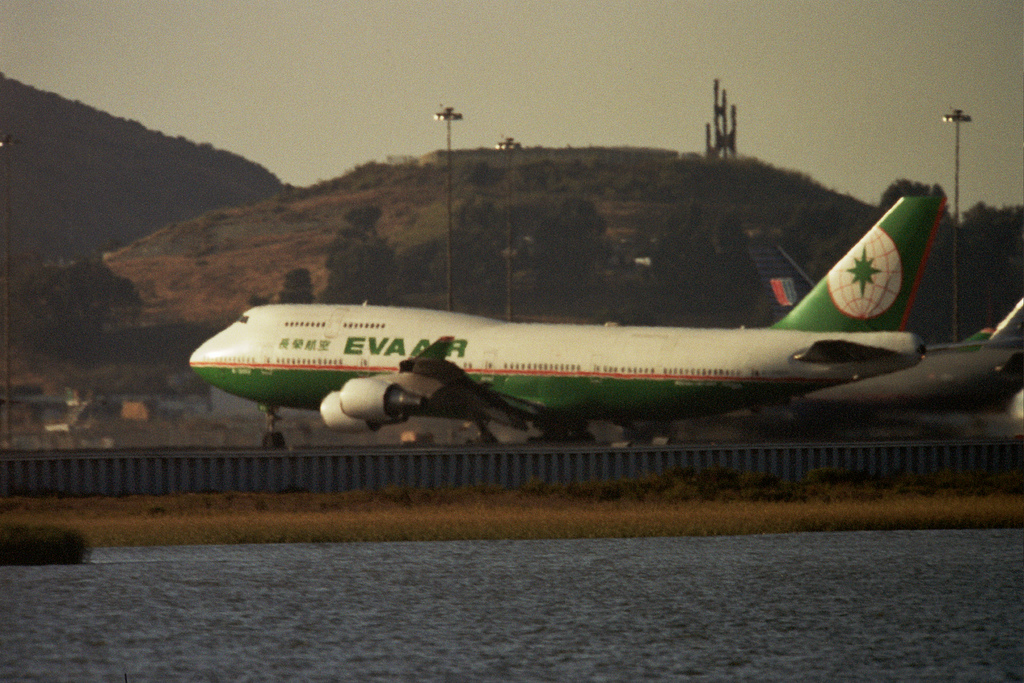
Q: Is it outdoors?
A: Yes, it is outdoors.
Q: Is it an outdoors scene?
A: Yes, it is outdoors.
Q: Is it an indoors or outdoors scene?
A: It is outdoors.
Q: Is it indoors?
A: No, it is outdoors.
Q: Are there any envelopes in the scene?
A: No, there are no envelopes.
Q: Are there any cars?
A: No, there are no cars.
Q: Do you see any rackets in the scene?
A: No, there are no rackets.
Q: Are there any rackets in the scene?
A: No, there are no rackets.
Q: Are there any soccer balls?
A: No, there are no soccer balls.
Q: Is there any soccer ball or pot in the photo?
A: No, there are no soccer balls or pots.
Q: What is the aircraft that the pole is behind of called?
A: The aircraft is an airplane.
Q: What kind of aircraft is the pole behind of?
A: The pole is behind the airplane.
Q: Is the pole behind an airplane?
A: Yes, the pole is behind an airplane.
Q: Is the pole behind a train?
A: No, the pole is behind an airplane.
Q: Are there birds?
A: No, there are no birds.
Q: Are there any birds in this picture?
A: No, there are no birds.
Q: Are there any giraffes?
A: No, there are no giraffes.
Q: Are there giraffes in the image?
A: No, there are no giraffes.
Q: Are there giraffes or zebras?
A: No, there are no giraffes or zebras.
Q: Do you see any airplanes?
A: Yes, there is an airplane.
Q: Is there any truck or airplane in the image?
A: Yes, there is an airplane.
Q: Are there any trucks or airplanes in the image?
A: Yes, there is an airplane.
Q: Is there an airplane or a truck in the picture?
A: Yes, there is an airplane.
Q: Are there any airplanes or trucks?
A: Yes, there is an airplane.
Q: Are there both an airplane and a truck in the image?
A: No, there is an airplane but no trucks.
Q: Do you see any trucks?
A: No, there are no trucks.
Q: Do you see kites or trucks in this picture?
A: No, there are no trucks or kites.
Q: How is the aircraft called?
A: The aircraft is an airplane.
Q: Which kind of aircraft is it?
A: The aircraft is an airplane.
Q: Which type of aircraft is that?
A: This is an airplane.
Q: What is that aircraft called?
A: This is an airplane.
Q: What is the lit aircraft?
A: The aircraft is an airplane.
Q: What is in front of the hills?
A: The airplane is in front of the hills.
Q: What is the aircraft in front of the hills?
A: The aircraft is an airplane.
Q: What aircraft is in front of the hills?
A: The aircraft is an airplane.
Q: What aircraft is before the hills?
A: The aircraft is an airplane.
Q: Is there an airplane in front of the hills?
A: Yes, there is an airplane in front of the hills.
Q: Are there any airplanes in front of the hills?
A: Yes, there is an airplane in front of the hills.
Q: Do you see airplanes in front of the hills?
A: Yes, there is an airplane in front of the hills.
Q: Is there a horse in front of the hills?
A: No, there is an airplane in front of the hills.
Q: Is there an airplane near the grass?
A: Yes, there is an airplane near the grass.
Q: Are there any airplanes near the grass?
A: Yes, there is an airplane near the grass.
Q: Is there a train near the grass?
A: No, there is an airplane near the grass.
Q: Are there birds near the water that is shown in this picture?
A: No, there is an airplane near the water.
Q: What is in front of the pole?
A: The airplane is in front of the pole.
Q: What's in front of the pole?
A: The airplane is in front of the pole.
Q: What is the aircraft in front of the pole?
A: The aircraft is an airplane.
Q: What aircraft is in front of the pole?
A: The aircraft is an airplane.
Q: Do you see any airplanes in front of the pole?
A: Yes, there is an airplane in front of the pole.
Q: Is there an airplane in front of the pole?
A: Yes, there is an airplane in front of the pole.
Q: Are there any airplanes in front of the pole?
A: Yes, there is an airplane in front of the pole.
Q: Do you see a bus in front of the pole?
A: No, there is an airplane in front of the pole.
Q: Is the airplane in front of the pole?
A: Yes, the airplane is in front of the pole.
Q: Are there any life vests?
A: No, there are no life vests.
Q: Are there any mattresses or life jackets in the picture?
A: No, there are no life jackets or mattresses.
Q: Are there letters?
A: Yes, there are letters.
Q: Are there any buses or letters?
A: Yes, there are letters.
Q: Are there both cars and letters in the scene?
A: No, there are letters but no cars.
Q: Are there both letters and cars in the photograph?
A: No, there are letters but no cars.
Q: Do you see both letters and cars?
A: No, there are letters but no cars.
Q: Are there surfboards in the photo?
A: No, there are no surfboards.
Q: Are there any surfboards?
A: No, there are no surfboards.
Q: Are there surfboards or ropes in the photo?
A: No, there are no surfboards or ropes.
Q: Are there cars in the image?
A: No, there are no cars.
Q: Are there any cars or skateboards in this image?
A: No, there are no cars or skateboards.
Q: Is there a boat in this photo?
A: No, there are no boats.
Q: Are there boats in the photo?
A: No, there are no boats.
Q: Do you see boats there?
A: No, there are no boats.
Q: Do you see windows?
A: Yes, there are windows.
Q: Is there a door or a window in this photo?
A: Yes, there are windows.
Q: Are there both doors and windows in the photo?
A: No, there are windows but no doors.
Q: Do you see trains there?
A: No, there are no trains.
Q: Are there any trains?
A: No, there are no trains.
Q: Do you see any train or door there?
A: No, there are no trains or doors.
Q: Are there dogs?
A: No, there are no dogs.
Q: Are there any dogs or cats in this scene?
A: No, there are no dogs or cats.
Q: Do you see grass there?
A: Yes, there is grass.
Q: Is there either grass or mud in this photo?
A: Yes, there is grass.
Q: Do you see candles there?
A: No, there are no candles.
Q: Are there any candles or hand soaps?
A: No, there are no candles or hand soaps.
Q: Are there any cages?
A: No, there are no cages.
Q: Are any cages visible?
A: No, there are no cages.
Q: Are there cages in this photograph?
A: No, there are no cages.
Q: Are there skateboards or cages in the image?
A: No, there are no cages or skateboards.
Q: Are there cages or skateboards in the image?
A: No, there are no cages or skateboards.